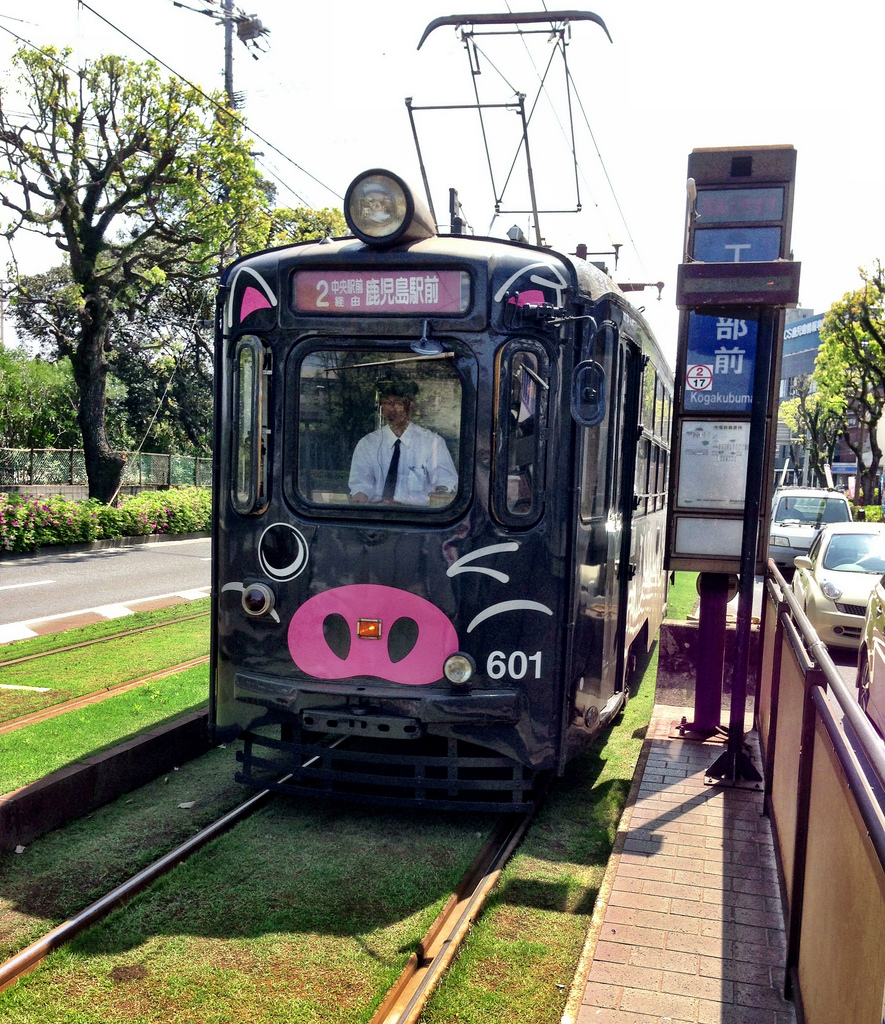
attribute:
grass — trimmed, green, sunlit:
[3, 651, 194, 742]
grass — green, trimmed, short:
[36, 769, 529, 1021]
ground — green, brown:
[88, 937, 380, 1020]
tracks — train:
[16, 743, 561, 1018]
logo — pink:
[281, 578, 466, 685]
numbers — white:
[480, 647, 547, 685]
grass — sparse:
[1, 599, 660, 1022]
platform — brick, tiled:
[552, 701, 799, 1021]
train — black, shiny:
[195, 172, 684, 823]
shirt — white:
[340, 415, 470, 529]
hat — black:
[374, 370, 427, 410]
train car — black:
[182, 159, 679, 821]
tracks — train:
[16, 717, 558, 1014]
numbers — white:
[485, 645, 552, 682]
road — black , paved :
[11, 526, 234, 628]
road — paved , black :
[3, 521, 233, 633]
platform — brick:
[589, 653, 809, 1019]